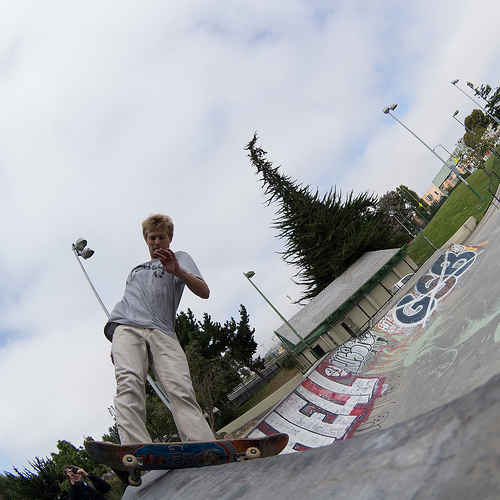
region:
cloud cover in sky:
[4, 1, 496, 437]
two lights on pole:
[72, 237, 112, 317]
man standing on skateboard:
[87, 212, 289, 487]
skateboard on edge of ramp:
[86, 376, 495, 498]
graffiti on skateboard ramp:
[246, 241, 476, 457]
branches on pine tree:
[247, 136, 404, 292]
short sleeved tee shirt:
[106, 250, 204, 338]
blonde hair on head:
[141, 214, 175, 256]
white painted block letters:
[254, 367, 379, 454]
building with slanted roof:
[278, 245, 415, 362]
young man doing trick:
[85, 210, 239, 477]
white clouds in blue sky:
[11, 19, 73, 71]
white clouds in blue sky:
[25, 96, 107, 157]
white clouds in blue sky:
[19, 369, 81, 413]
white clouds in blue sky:
[8, 144, 106, 185]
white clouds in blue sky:
[158, 123, 225, 193]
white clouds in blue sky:
[118, 30, 229, 84]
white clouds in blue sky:
[259, 36, 374, 74]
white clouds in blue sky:
[288, 94, 376, 165]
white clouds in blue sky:
[341, 19, 419, 60]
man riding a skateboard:
[85, 216, 287, 486]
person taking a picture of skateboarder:
[58, 465, 112, 498]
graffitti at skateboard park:
[242, 235, 488, 455]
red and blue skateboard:
[83, 432, 288, 485]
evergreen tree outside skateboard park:
[242, 133, 409, 305]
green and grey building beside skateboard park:
[263, 243, 414, 368]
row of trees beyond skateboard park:
[0, 305, 255, 498]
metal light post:
[71, 238, 172, 409]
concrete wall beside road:
[216, 218, 476, 434]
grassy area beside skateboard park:
[404, 153, 497, 264]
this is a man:
[65, 198, 236, 463]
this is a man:
[57, 465, 112, 497]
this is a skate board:
[70, 423, 312, 471]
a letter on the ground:
[377, 280, 430, 329]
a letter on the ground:
[412, 269, 461, 302]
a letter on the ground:
[422, 240, 486, 282]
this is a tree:
[470, 80, 498, 119]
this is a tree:
[235, 120, 418, 306]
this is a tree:
[181, 291, 293, 394]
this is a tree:
[47, 430, 104, 498]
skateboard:
[76, 433, 292, 485]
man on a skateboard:
[96, 208, 231, 459]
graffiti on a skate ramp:
[231, 234, 483, 456]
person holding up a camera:
[60, 460, 115, 499]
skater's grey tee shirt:
[100, 246, 209, 331]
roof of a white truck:
[383, 268, 420, 295]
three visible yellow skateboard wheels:
[115, 445, 261, 492]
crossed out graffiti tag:
[383, 243, 494, 328]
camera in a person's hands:
[63, 464, 83, 476]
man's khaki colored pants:
[102, 317, 216, 447]